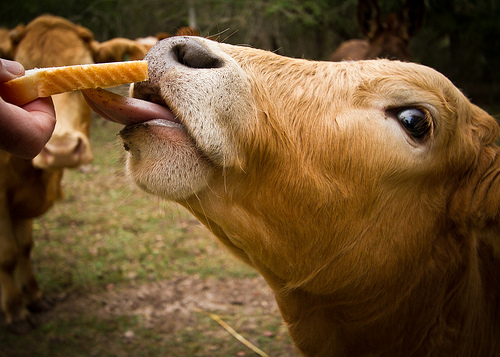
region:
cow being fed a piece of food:
[12, 25, 477, 330]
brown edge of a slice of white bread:
[5, 45, 160, 96]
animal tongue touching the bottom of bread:
[60, 70, 185, 140]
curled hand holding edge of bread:
[2, 40, 67, 172]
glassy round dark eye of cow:
[375, 85, 441, 156]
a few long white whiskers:
[146, 116, 259, 236]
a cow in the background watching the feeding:
[7, 15, 152, 195]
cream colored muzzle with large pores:
[116, 26, 261, 217]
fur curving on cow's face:
[251, 110, 376, 305]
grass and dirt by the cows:
[50, 208, 222, 344]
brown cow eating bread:
[80, 32, 498, 346]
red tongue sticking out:
[83, 84, 172, 126]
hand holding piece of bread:
[3, 52, 57, 172]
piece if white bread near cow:
[3, 52, 150, 106]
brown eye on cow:
[391, 100, 431, 145]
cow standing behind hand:
[0, 12, 151, 320]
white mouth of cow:
[116, 32, 255, 199]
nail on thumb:
[1, 55, 28, 82]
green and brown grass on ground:
[0, 67, 293, 352]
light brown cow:
[126, 28, 498, 353]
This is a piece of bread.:
[0, 50, 164, 90]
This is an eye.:
[365, 65, 441, 153]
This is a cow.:
[93, 52, 469, 329]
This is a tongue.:
[81, 79, 190, 135]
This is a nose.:
[141, 35, 270, 102]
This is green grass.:
[78, 207, 158, 307]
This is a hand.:
[0, 52, 67, 164]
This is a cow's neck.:
[284, 230, 496, 352]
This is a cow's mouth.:
[111, 70, 216, 177]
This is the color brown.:
[291, 182, 401, 291]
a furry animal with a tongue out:
[111, 23, 497, 355]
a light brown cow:
[3, 10, 130, 316]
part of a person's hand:
[0, 54, 63, 168]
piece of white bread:
[3, 56, 155, 96]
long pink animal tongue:
[78, 79, 172, 132]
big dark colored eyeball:
[383, 95, 440, 154]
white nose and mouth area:
[118, 31, 260, 209]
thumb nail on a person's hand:
[3, 57, 23, 77]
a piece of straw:
[208, 312, 269, 355]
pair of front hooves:
[3, 288, 63, 338]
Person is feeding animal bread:
[2, 32, 497, 352]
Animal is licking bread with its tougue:
[56, 22, 496, 352]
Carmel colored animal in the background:
[0, 7, 150, 337]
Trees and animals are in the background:
[103, 3, 498, 84]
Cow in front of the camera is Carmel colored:
[117, 30, 497, 353]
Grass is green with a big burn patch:
[16, 164, 293, 354]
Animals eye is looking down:
[370, 82, 445, 160]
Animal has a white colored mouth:
[116, 24, 260, 215]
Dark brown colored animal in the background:
[316, 0, 445, 71]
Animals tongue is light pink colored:
[82, 81, 188, 136]